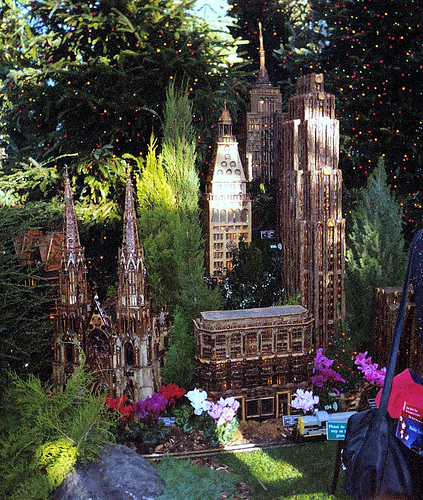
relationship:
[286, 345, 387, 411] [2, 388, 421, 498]
flowers on ground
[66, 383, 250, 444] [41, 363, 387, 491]
flowers on ground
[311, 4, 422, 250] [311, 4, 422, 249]
beads hanging in tree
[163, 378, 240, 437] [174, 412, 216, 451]
flowers with leaves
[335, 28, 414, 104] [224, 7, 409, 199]
lights in tree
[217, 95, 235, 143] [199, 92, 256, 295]
tower on building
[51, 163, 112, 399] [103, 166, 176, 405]
building of building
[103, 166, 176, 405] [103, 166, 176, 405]
building of building